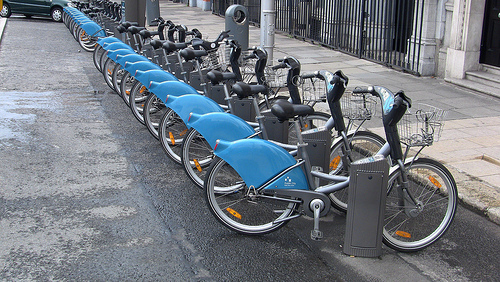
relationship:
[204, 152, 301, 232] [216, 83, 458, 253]
wheel of bike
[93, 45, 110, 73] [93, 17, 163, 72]
wheel of bike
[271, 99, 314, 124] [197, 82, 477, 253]
seat on bicycle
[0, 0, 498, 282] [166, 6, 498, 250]
sidewalk near sidewalk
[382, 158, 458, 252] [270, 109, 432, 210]
wheel of bicycle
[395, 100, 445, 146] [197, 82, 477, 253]
basket on bicycle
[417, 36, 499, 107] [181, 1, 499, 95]
steps by building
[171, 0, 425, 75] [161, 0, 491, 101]
fence by building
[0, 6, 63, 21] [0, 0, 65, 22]
wheel on car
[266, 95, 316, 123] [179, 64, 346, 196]
seat on bicycle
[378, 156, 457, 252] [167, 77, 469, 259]
wheel on bike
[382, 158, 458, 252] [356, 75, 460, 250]
wheel on bike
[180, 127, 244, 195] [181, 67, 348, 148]
wheel on bike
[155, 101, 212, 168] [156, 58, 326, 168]
wheel on bike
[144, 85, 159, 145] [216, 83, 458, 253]
wheel on bike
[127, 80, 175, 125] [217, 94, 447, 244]
wheel on bike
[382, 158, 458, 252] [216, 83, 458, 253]
wheel on bike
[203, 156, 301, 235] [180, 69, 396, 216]
wheel on bike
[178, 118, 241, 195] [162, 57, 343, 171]
wheel on bike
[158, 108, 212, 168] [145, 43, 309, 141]
wheel on bike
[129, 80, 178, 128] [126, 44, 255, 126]
wheel on bike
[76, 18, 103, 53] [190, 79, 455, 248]
wheel on bike